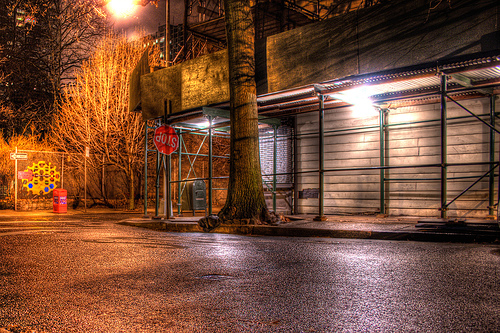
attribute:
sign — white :
[10, 153, 31, 162]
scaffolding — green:
[141, 13, 498, 66]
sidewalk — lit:
[293, 208, 428, 235]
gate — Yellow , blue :
[18, 150, 91, 242]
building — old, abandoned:
[123, 15, 495, 253]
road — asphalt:
[7, 231, 497, 323]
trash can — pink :
[50, 184, 70, 215]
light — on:
[351, 96, 377, 123]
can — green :
[183, 177, 208, 214]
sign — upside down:
[151, 124, 183, 155]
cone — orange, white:
[49, 185, 69, 215]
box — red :
[52, 188, 63, 199]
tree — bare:
[52, 23, 161, 214]